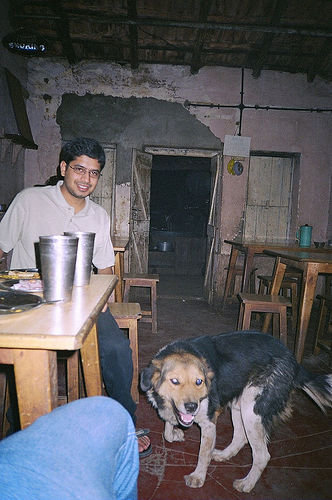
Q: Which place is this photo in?
A: It is at the restaurant.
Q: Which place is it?
A: It is a restaurant.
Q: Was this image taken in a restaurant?
A: Yes, it was taken in a restaurant.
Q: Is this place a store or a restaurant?
A: It is a restaurant.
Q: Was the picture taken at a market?
A: No, the picture was taken in a restaurant.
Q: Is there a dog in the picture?
A: Yes, there is a dog.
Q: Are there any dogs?
A: Yes, there is a dog.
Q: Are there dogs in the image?
A: Yes, there is a dog.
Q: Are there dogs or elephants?
A: Yes, there is a dog.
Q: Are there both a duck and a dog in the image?
A: No, there is a dog but no ducks.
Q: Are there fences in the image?
A: No, there are no fences.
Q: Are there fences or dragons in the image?
A: No, there are no fences or dragons.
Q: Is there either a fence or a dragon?
A: No, there are no fences or dragons.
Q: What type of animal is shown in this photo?
A: The animal is a dog.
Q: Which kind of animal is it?
A: The animal is a dog.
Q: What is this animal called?
A: That is a dog.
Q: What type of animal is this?
A: That is a dog.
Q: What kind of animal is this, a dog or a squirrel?
A: That is a dog.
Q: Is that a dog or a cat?
A: That is a dog.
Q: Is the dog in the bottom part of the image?
A: Yes, the dog is in the bottom of the image.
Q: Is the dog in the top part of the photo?
A: No, the dog is in the bottom of the image.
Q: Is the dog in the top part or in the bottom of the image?
A: The dog is in the bottom of the image.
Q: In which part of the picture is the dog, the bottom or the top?
A: The dog is in the bottom of the image.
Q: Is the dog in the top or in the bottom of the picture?
A: The dog is in the bottom of the image.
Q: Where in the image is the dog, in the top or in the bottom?
A: The dog is in the bottom of the image.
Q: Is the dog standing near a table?
A: Yes, the dog is standing near a table.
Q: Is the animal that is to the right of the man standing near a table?
A: Yes, the dog is standing near a table.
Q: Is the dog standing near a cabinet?
A: No, the dog is standing near a table.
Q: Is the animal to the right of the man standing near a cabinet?
A: No, the dog is standing near a table.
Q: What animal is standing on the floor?
A: The dog is standing on the floor.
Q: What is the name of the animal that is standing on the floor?
A: The animal is a dog.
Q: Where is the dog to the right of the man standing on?
A: The dog is standing on the floor.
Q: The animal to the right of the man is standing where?
A: The dog is standing on the floor.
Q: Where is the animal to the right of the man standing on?
A: The dog is standing on the floor.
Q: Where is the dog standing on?
A: The dog is standing on the floor.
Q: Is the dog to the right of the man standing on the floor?
A: Yes, the dog is standing on the floor.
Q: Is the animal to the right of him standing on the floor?
A: Yes, the dog is standing on the floor.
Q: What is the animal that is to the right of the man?
A: The animal is a dog.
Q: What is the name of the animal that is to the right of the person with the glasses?
A: The animal is a dog.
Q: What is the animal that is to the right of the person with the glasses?
A: The animal is a dog.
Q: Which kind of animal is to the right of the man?
A: The animal is a dog.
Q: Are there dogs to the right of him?
A: Yes, there is a dog to the right of the man.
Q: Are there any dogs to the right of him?
A: Yes, there is a dog to the right of the man.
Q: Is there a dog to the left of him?
A: No, the dog is to the right of the man.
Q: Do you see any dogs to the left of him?
A: No, the dog is to the right of the man.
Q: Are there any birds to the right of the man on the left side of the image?
A: No, there is a dog to the right of the man.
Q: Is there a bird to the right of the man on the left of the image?
A: No, there is a dog to the right of the man.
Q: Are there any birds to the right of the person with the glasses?
A: No, there is a dog to the right of the man.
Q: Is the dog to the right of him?
A: Yes, the dog is to the right of a man.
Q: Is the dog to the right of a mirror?
A: No, the dog is to the right of a man.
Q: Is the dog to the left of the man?
A: No, the dog is to the right of the man.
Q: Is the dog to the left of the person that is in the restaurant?
A: No, the dog is to the right of the man.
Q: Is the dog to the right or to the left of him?
A: The dog is to the right of the man.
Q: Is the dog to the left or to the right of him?
A: The dog is to the right of the man.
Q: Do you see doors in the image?
A: Yes, there is a door.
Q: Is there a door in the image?
A: Yes, there is a door.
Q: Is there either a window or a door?
A: Yes, there is a door.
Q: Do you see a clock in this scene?
A: No, there are no clocks.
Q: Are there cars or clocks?
A: No, there are no clocks or cars.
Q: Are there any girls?
A: No, there are no girls.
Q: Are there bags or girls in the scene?
A: No, there are no girls or bags.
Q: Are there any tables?
A: Yes, there is a table.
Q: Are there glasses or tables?
A: Yes, there is a table.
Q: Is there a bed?
A: No, there are no beds.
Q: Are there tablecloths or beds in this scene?
A: No, there are no beds or tablecloths.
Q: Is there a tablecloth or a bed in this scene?
A: No, there are no beds or tablecloths.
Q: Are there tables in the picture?
A: Yes, there is a table.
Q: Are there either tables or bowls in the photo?
A: Yes, there is a table.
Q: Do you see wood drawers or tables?
A: Yes, there is a wood table.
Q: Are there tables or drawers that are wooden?
A: Yes, the table is wooden.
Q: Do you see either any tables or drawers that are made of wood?
A: Yes, the table is made of wood.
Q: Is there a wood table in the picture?
A: Yes, there is a wood table.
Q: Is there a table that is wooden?
A: Yes, there is a table that is wooden.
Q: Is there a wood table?
A: Yes, there is a table that is made of wood.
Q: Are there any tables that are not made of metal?
A: Yes, there is a table that is made of wood.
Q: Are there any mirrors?
A: No, there are no mirrors.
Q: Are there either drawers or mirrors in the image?
A: No, there are no mirrors or drawers.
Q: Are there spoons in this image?
A: No, there are no spoons.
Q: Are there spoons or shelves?
A: No, there are no spoons or shelves.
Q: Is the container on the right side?
A: Yes, the container is on the right of the image.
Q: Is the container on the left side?
A: No, the container is on the right of the image.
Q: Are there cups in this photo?
A: Yes, there is a cup.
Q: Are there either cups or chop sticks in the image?
A: Yes, there is a cup.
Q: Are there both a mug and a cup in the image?
A: No, there is a cup but no mugs.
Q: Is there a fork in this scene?
A: No, there are no forks.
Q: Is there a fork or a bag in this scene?
A: No, there are no forks or bags.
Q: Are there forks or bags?
A: No, there are no forks or bags.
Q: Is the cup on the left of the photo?
A: Yes, the cup is on the left of the image.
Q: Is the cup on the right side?
A: No, the cup is on the left of the image.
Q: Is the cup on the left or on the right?
A: The cup is on the left of the image.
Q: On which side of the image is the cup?
A: The cup is on the left of the image.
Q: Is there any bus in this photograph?
A: No, there are no buses.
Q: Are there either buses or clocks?
A: No, there are no buses or clocks.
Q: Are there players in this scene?
A: No, there are no players.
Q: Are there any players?
A: No, there are no players.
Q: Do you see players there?
A: No, there are no players.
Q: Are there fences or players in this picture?
A: No, there are no players or fences.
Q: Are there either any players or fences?
A: No, there are no players or fences.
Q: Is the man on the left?
A: Yes, the man is on the left of the image.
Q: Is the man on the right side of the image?
A: No, the man is on the left of the image.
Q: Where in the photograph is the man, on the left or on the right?
A: The man is on the left of the image.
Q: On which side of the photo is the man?
A: The man is on the left of the image.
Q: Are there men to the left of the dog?
A: Yes, there is a man to the left of the dog.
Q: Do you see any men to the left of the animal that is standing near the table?
A: Yes, there is a man to the left of the dog.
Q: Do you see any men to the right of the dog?
A: No, the man is to the left of the dog.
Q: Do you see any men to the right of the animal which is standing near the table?
A: No, the man is to the left of the dog.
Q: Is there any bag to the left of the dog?
A: No, there is a man to the left of the dog.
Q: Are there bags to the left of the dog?
A: No, there is a man to the left of the dog.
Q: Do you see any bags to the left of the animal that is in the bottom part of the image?
A: No, there is a man to the left of the dog.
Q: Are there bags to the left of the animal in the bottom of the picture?
A: No, there is a man to the left of the dog.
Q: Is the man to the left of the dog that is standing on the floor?
A: Yes, the man is to the left of the dog.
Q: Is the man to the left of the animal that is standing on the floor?
A: Yes, the man is to the left of the dog.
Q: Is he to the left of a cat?
A: No, the man is to the left of the dog.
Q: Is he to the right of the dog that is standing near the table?
A: No, the man is to the left of the dog.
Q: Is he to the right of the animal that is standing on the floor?
A: No, the man is to the left of the dog.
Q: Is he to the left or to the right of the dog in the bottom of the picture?
A: The man is to the left of the dog.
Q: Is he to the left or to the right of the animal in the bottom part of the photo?
A: The man is to the left of the dog.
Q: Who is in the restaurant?
A: The man is in the restaurant.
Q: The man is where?
A: The man is in the restaurant.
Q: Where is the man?
A: The man is in the restaurant.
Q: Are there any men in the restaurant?
A: Yes, there is a man in the restaurant.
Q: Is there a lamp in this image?
A: No, there are no lamps.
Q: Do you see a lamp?
A: No, there are no lamps.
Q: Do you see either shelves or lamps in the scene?
A: No, there are no lamps or shelves.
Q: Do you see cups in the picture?
A: Yes, there is a cup.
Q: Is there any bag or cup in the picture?
A: Yes, there is a cup.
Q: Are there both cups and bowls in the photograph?
A: No, there is a cup but no bowls.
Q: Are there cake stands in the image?
A: No, there are no cake stands.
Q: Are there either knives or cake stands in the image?
A: No, there are no cake stands or knives.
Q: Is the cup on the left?
A: Yes, the cup is on the left of the image.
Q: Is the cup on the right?
A: No, the cup is on the left of the image.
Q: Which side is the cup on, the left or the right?
A: The cup is on the left of the image.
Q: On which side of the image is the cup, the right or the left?
A: The cup is on the left of the image.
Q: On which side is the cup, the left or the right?
A: The cup is on the left of the image.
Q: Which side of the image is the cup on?
A: The cup is on the left of the image.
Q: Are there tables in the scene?
A: Yes, there is a table.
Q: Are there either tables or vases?
A: Yes, there is a table.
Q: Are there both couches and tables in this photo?
A: No, there is a table but no couches.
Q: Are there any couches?
A: No, there are no couches.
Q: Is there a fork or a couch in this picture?
A: No, there are no couches or forks.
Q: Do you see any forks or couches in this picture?
A: No, there are no couches or forks.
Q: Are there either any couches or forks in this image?
A: No, there are no couches or forks.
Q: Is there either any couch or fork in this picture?
A: No, there are no couches or forks.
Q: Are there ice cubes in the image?
A: No, there are no ice cubes.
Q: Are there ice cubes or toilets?
A: No, there are no ice cubes or toilets.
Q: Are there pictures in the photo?
A: No, there are no pictures.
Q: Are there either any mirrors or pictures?
A: No, there are no pictures or mirrors.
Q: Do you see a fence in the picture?
A: No, there are no fences.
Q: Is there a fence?
A: No, there are no fences.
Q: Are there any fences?
A: No, there are no fences.